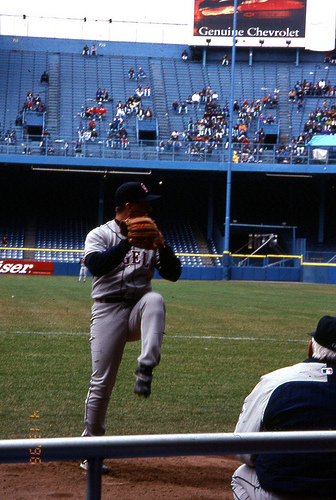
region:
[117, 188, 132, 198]
man wearing blue hat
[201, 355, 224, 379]
green grass in field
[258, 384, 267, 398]
white part of jacket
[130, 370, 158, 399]
man wearing black sneakers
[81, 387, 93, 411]
blue stripe on pants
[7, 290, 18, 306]
A small ball on the grass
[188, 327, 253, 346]
A thin line on the grass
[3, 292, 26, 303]
A white ball on the grass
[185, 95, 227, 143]
People watching at the bench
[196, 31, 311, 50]
Lights below the big screen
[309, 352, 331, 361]
Tip of the white hair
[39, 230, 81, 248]
There are empty blue chairs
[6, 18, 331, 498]
a scene outside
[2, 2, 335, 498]
a photo of a baseball field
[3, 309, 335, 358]
a white line on the ground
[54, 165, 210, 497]
a pitcher winding up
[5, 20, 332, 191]
a stadium with some people in background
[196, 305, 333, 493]
an old man with a cap kneeling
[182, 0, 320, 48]
a billboard on top of stadium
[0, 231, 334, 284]
a yellow tape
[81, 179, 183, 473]
baseball player poised to throw the ball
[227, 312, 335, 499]
man crouched down on his knees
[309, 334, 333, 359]
straggly white hair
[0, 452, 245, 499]
baseball dirt mound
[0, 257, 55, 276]
part of a Budweiser advertisement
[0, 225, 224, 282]
empty baseball stands on the first level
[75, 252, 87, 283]
baseball player in the distance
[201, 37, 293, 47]
four flood lights above baseball stadium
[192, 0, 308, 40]
Chevrolet billboard advertisement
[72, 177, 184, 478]
A baseball pitcher at a baseball field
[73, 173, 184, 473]
A baseball pitcher at a baseball field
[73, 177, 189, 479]
A baseball pitcher at a baseball field